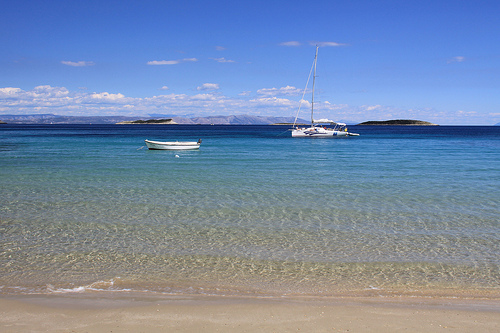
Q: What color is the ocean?
A: Blue.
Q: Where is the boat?
A: In the water.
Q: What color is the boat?
A: White.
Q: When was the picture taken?
A: During the day.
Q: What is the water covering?
A: The sand.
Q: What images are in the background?
A: Mountains.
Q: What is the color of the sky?
A: Blue.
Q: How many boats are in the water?
A: Two.